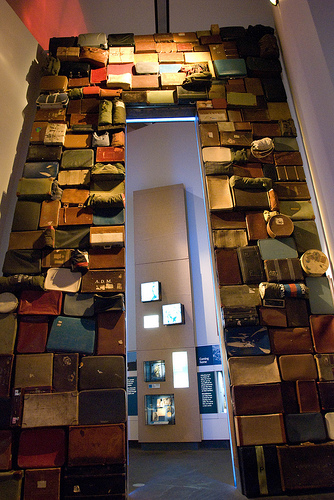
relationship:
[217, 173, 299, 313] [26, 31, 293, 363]
wallets on display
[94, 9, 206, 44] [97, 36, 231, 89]
light on wallets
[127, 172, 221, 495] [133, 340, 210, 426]
frames reflected mirror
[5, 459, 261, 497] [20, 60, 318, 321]
writing on wall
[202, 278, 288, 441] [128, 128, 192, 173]
writing on wall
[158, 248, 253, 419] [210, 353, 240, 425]
writing on wall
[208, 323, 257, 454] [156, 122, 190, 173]
writing on wall